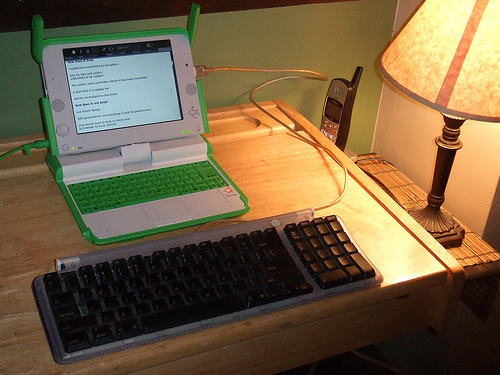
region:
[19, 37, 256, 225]
an old white laptop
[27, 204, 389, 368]
a small black keyboard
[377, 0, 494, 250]
a small dim lamp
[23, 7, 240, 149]
a laptop screenw ith antennas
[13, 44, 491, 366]
the surface of a desk top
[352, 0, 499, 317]
a sidetable with a lamp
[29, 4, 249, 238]
a green and white laptop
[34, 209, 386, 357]
a computer keyboard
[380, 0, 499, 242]
the lamp is on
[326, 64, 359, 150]
a cordless telephone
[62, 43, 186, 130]
the laptop screen is on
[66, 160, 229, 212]
laptop has a green keyboard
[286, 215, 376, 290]
number pad on the keyboard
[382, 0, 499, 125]
the lamp shade is beige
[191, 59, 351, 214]
a wire attached to the laptop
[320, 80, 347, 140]
the phone is silver in the front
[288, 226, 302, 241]
button on computer keyboard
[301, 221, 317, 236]
button on computer keyboard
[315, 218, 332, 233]
button on computer keyboard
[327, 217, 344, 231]
button on computer keyboard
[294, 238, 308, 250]
button on computer keyboard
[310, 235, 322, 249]
button on computer keyboard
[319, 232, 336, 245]
button on computer keyboard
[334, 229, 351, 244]
button on computer keyboard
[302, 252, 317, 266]
button on computer keyboard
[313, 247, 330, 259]
button on computer keyboard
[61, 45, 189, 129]
screen on a green and grey computer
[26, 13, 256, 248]
green and grey computer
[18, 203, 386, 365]
keyboard on a desk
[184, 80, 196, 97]
speaker on the right side of the screen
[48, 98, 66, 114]
speaker on the left side of the screen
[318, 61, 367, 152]
cordless phone near a desk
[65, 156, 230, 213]
green keyboard on a computer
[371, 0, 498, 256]
lamp on the side of the desk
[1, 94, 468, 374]
wooden desk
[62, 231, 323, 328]
black keyboard on desk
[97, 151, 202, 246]
green keys on laptop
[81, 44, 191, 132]
screen on small laptop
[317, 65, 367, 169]
black phone near desk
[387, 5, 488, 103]
light has white shade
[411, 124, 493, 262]
black frame for lamp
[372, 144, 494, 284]
lamp on brown table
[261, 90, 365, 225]
grey cord on laptop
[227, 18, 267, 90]
green wall behind laptop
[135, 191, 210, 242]
white touchpad on laptop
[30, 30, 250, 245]
an old small laptop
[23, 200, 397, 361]
an old computer keyboard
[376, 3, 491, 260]
a dimly lit lamp with a light on